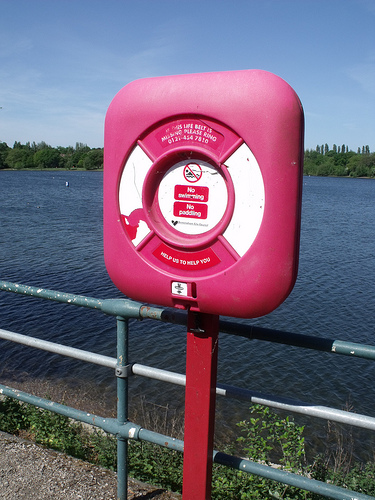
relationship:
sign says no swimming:
[103, 69, 302, 311] [180, 162, 204, 183]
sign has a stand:
[103, 69, 302, 311] [183, 311, 211, 496]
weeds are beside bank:
[233, 401, 312, 493] [138, 442, 364, 499]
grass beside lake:
[14, 371, 190, 438] [2, 168, 373, 458]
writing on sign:
[155, 251, 217, 267] [103, 69, 302, 311]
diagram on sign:
[115, 110, 266, 282] [103, 69, 302, 311]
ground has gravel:
[2, 396, 303, 499] [4, 434, 186, 496]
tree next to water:
[323, 143, 329, 157] [2, 168, 373, 458]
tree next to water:
[340, 143, 346, 156] [2, 168, 373, 458]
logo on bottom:
[171, 280, 187, 297] [103, 239, 296, 317]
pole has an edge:
[183, 311, 211, 496] [204, 315, 218, 499]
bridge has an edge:
[0, 277, 373, 499] [4, 378, 252, 499]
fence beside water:
[0, 277, 373, 499] [2, 168, 373, 458]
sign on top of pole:
[103, 69, 302, 311] [183, 311, 211, 496]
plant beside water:
[0, 396, 29, 434] [2, 168, 373, 458]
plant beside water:
[26, 403, 80, 455] [2, 168, 373, 458]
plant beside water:
[85, 432, 157, 475] [2, 168, 373, 458]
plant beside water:
[233, 401, 312, 493] [2, 168, 373, 458]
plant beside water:
[313, 438, 374, 493] [2, 168, 373, 458]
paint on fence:
[15, 284, 43, 296] [0, 277, 373, 499]